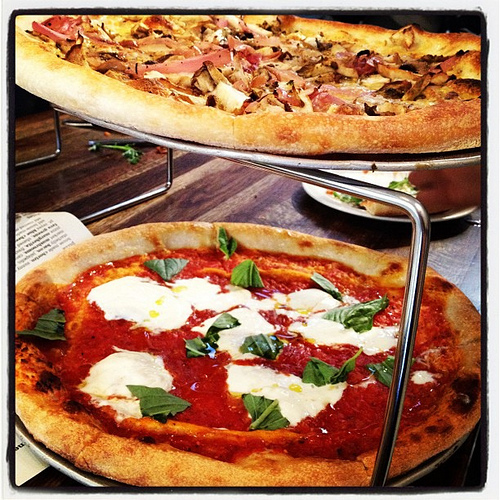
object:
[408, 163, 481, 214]
person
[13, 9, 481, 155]
pizza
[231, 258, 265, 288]
basil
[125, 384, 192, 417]
basil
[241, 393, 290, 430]
basil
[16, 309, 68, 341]
basil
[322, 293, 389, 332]
basil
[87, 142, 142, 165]
food bits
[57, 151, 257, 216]
wooden table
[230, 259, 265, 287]
basil leaf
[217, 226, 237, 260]
basil leaf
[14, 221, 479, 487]
pizza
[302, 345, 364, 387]
leaves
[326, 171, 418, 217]
pizza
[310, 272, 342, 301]
green leaf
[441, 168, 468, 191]
ground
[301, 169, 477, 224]
plate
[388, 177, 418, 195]
salad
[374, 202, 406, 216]
crust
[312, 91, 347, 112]
red onion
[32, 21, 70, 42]
red onion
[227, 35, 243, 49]
red onion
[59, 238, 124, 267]
pizza crust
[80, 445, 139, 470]
pizza crust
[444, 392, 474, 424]
pizza crust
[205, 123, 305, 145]
pizza crust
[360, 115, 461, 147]
pizza crust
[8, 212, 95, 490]
paper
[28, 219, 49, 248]
words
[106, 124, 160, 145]
wall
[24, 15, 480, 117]
mushrooms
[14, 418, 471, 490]
plate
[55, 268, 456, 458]
sauce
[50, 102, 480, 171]
plate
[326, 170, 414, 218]
slice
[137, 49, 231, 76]
ham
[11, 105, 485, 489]
rack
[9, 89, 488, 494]
table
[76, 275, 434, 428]
mozzarella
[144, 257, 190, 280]
basil